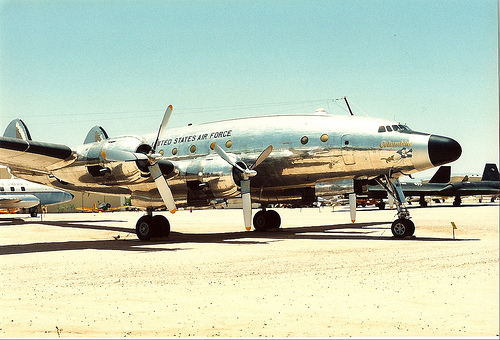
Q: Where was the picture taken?
A: It was taken at the runway.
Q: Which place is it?
A: It is a runway.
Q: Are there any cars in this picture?
A: No, there are no cars.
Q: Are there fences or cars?
A: No, there are no cars or fences.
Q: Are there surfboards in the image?
A: No, there are no surfboards.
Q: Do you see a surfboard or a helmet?
A: No, there are no surfboards or helmets.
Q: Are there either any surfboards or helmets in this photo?
A: No, there are no surfboards or helmets.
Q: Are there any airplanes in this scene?
A: Yes, there is an airplane.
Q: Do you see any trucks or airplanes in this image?
A: Yes, there is an airplane.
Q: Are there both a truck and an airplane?
A: No, there is an airplane but no trucks.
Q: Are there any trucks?
A: No, there are no trucks.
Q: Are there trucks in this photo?
A: No, there are no trucks.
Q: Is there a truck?
A: No, there are no trucks.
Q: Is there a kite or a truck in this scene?
A: No, there are no trucks or kites.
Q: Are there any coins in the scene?
A: No, there are no coins.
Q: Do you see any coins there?
A: No, there are no coins.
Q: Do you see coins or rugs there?
A: No, there are no coins or rugs.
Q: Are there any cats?
A: No, there are no cats.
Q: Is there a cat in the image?
A: No, there are no cats.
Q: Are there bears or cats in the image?
A: No, there are no cats or bears.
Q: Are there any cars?
A: No, there are no cars.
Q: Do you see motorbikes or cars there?
A: No, there are no cars or motorbikes.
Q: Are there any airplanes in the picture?
A: Yes, there is an airplane.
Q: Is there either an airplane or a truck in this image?
A: Yes, there is an airplane.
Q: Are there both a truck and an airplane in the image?
A: No, there is an airplane but no trucks.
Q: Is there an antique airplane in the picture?
A: Yes, there is an antique airplane.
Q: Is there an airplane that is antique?
A: Yes, there is an airplane that is antique.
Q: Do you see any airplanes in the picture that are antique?
A: Yes, there is an airplane that is antique.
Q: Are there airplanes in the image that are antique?
A: Yes, there is an airplane that is antique.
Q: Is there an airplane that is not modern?
A: Yes, there is a antique airplane.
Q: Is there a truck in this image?
A: No, there are no trucks.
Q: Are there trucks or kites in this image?
A: No, there are no trucks or kites.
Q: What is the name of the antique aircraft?
A: The aircraft is an airplane.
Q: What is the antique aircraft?
A: The aircraft is an airplane.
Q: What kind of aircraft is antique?
A: The aircraft is an airplane.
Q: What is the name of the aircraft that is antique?
A: The aircraft is an airplane.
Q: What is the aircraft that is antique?
A: The aircraft is an airplane.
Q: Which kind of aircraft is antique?
A: The aircraft is an airplane.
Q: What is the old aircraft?
A: The aircraft is an airplane.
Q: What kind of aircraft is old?
A: The aircraft is an airplane.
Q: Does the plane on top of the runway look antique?
A: Yes, the plane is antique.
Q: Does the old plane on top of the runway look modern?
A: No, the airplane is antique.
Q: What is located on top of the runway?
A: The airplane is on top of the runway.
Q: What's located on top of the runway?
A: The airplane is on top of the runway.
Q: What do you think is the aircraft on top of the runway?
A: The aircraft is an airplane.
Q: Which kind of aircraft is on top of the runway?
A: The aircraft is an airplane.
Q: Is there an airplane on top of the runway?
A: Yes, there is an airplane on top of the runway.